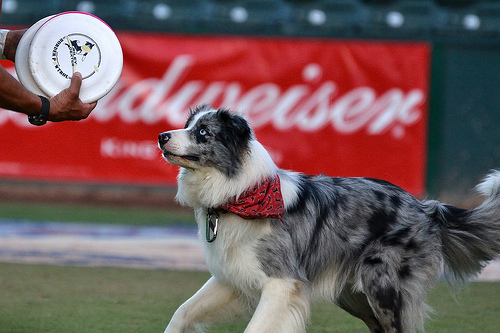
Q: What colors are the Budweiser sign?
A: Red, white.